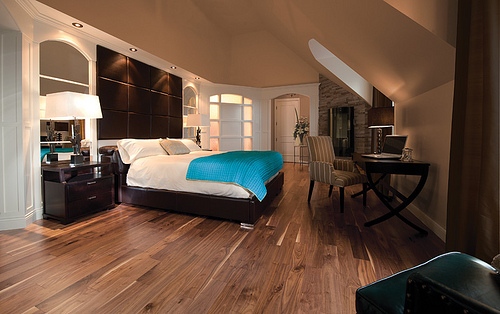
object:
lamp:
[43, 90, 105, 163]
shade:
[42, 88, 103, 121]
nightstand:
[41, 157, 120, 225]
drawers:
[66, 192, 118, 220]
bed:
[98, 132, 289, 222]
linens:
[114, 131, 285, 198]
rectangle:
[93, 43, 133, 86]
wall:
[6, 1, 226, 225]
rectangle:
[98, 110, 131, 138]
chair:
[293, 134, 365, 208]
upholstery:
[303, 133, 370, 214]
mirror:
[38, 94, 93, 164]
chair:
[352, 249, 500, 311]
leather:
[353, 250, 498, 313]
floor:
[0, 150, 447, 312]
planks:
[0, 15, 35, 229]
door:
[271, 91, 311, 160]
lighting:
[37, 29, 102, 84]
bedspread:
[184, 147, 286, 203]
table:
[352, 146, 433, 236]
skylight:
[307, 33, 398, 106]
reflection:
[39, 93, 74, 156]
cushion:
[317, 160, 365, 186]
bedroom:
[0, 0, 498, 313]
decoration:
[95, 42, 187, 140]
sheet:
[125, 145, 286, 203]